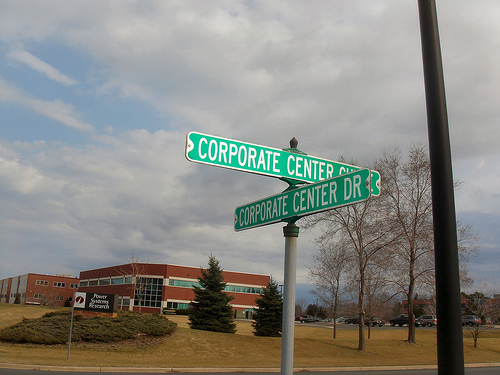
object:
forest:
[296, 137, 498, 350]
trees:
[375, 138, 480, 343]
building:
[399, 298, 437, 316]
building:
[460, 292, 498, 319]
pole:
[278, 137, 306, 374]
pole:
[67, 303, 75, 366]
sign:
[72, 291, 120, 313]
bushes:
[0, 309, 177, 347]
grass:
[0, 302, 178, 344]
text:
[232, 167, 370, 235]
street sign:
[232, 168, 370, 231]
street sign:
[183, 130, 380, 198]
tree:
[184, 253, 239, 336]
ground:
[0, 302, 499, 368]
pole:
[413, 0, 468, 374]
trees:
[314, 141, 417, 352]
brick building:
[74, 262, 274, 321]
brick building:
[0, 272, 82, 308]